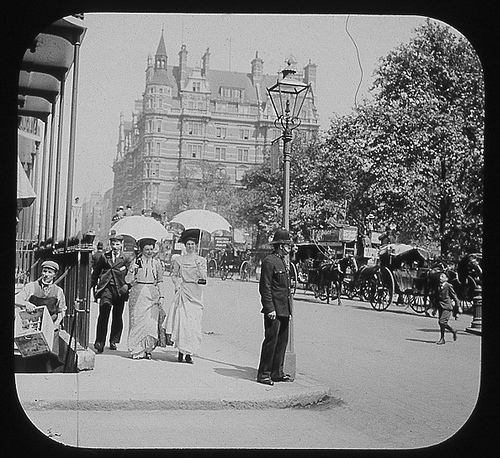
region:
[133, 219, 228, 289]
the two ladies are walking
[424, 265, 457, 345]
he is crossing the street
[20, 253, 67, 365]
he's carring a crate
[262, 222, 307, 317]
the policeman is standing at the corner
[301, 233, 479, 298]
the horse carriages are lined up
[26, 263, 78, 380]
he walking up stairs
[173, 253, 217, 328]
she's holding her dress up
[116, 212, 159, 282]
she's carring an umbrella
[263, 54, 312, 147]
the light is not on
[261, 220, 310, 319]
the policeman is watching at the corner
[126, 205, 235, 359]
Women carrying parasols wearing long dresses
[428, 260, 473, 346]
Young boy crossing the street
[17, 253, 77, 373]
A worker carrying a box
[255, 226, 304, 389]
A policeman standing on the corner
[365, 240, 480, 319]
A horse and buggy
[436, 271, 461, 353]
young boy wearing knickers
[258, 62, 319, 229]
an old fashioned lampost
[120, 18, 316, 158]
an old building with a cathedral ceiling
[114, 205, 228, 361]
Two women walking down the sidewalk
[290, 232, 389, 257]
Old building selling goods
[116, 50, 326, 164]
large castlelike building in background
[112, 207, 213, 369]
ladies in dresses walking with umbrellas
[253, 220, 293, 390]
police officer standing on street corner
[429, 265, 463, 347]
child running across the road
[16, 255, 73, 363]
man carrying a crate upstairs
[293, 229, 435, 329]
two horse and carriages going down the road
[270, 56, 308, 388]
tall wrought iron streetlight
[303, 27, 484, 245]
multiple tall standing trees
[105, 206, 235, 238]
two white opened umbrellas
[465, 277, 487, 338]
fire hydrant on street corner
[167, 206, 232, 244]
an open white umbrella.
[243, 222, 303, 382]
a man standing on a corner.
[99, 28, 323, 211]
a tall multi story building.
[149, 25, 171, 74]
a tower on top of a building.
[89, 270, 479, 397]
a road with people walking across it.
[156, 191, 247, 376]
a woman holding a white umbrella.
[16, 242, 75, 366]
A person sitting near a building.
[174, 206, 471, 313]
a crowd of people standing on the side of a road.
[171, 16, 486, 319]
a tree filled park.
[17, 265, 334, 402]
a sidewalk near a street.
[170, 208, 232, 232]
the top of a light colored woman's umbrella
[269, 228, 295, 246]
a vintage fireman's hat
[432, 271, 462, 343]
a young boy crossing the street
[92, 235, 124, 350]
a mail carrier on the street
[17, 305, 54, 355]
a wooden box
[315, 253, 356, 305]
a horse on the street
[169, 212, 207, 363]
a lady in a dress holding an umbrella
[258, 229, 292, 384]
a fireman in his fire hat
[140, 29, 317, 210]
a very large building in black and white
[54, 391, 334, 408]
an inner city street curb